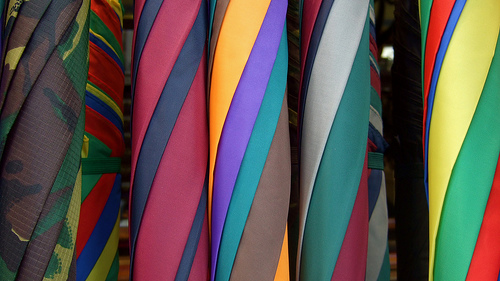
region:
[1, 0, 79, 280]
Green and brown camouflage umbrella.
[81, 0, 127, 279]
Red, blue, yellow, and green umbrella.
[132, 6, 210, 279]
Pink and blue umbrella.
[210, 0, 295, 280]
Yellow, purple, green and grey umbrella.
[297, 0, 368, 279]
Maroon, blue, white, and teal umbrella.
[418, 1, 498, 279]
Red, blue, yellow, and green umbrella.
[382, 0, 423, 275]
Dark background behind umbrellas.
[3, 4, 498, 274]
Group of multi-colored umbrellas.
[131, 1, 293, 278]
Two colorful umbrellas.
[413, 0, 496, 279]
Brightly colored umbrella.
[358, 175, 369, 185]
part of a curtain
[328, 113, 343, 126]
edge of a curtain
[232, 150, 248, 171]
part of an umbrella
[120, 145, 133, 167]
part of a surface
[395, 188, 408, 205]
edge of a surface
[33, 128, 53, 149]
side of an umbrella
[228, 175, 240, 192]
edge of a wall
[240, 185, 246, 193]
part of a tissue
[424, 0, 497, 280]
yellow stripe right side of photo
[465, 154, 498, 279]
red stripe bottom right corner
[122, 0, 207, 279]
red and blue twisted cloth pieces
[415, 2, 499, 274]
green red blue and yellow twisted cloth pieces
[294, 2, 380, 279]
red blue gray green twisted cloth pieces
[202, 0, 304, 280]
brown yellow purple blue twisted cloth pieces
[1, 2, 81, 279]
twisted green and brown camouflaged cloth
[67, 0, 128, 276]
red blue yellow green twisted cloth sections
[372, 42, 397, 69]
distant light source in background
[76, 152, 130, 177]
horizontal green cloth strap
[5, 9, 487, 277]
colorful ties aligned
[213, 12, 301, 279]
multi colored tie shown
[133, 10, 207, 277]
multi colored tie shown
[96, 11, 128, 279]
multi colored tie shown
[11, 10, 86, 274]
multi colored tie shown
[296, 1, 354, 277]
multi colored tie shown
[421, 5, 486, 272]
multi colored tie shown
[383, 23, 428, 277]
space shown between ties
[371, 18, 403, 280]
multi colored tie shown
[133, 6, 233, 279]
red and blue stripes on tie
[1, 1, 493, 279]
bolts of mulit colored fabric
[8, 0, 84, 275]
green and brown camoflouge fabric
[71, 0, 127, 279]
green red blue and yellow striped fabric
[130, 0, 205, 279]
red and blue striped fabric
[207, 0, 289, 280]
yellow purple blue and brown striped fabric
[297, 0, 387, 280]
blue red white and teel striped fabric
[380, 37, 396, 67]
light peeking through fabrics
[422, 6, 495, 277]
yellow green blue and red striped fabric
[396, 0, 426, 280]
black bolt of fabric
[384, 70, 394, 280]
tiny sliver of what is on other side of fabrics